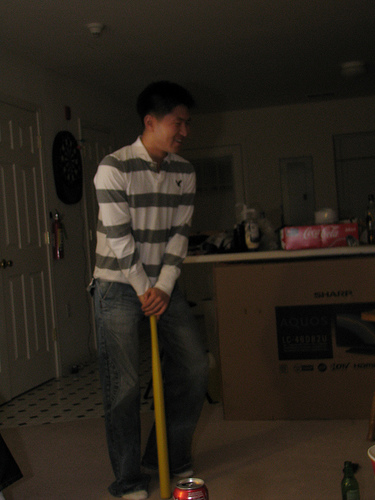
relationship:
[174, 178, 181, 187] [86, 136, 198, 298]
logo on shirt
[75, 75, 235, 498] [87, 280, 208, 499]
man wearing jeans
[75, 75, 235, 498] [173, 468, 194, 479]
man wearing sock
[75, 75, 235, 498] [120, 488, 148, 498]
man wearing sock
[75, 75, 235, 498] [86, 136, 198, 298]
man wearing shirt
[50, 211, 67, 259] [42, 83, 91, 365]
hydrant hanging on wall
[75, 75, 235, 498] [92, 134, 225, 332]
man wearing shirt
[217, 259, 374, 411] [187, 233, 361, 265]
box under counter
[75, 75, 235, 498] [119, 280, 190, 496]
man with bat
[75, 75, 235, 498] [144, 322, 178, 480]
man holding bat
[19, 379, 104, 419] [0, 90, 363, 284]
linoleum in kitchen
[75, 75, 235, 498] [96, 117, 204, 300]
man wearing shirt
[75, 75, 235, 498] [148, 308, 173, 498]
man holding stick